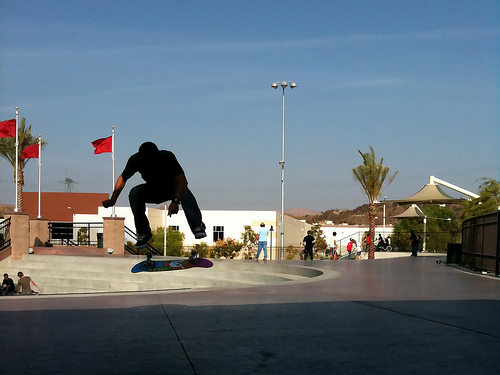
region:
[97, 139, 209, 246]
Guy in black skating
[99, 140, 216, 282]
Guy performing an ollie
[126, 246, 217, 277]
Blue and purple skateboard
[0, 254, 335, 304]
Oval set of concrete stairs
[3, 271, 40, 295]
Two people sitting on stairs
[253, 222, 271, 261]
Guy wearing a baby blue shirt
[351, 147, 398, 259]
Brown and green palm tree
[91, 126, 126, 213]
White flag pole with red flag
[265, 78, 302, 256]
Tall silver light pole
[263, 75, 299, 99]
Three lights at the top of light pole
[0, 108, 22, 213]
a nondescript red flag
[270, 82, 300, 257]
a very tall street lamp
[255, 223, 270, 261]
a man in blue walking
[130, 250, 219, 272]
a flipped skateboard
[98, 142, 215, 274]
a man doing a trick on his skateboard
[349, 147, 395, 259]
a warm weather tree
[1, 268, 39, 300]
two people sitting side by side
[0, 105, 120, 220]
three red flags waving side by side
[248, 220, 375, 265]
a group of distant people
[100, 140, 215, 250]
a man jumping in the air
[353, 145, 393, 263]
A palm tree.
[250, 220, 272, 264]
A man in jeans and a light blue shirt.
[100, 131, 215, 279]
A skateboarder doing tricks.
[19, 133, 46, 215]
A red flag.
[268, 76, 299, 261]
Outdoor lights.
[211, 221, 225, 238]
A window.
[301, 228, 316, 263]
A person dressed in black.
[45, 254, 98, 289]
The concrete stairs.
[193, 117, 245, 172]
The clear blue sky.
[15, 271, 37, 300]
A person sitting down with a brown shirt on.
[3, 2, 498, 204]
blue of daytime sky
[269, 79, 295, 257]
three lights on pole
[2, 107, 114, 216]
three red flags on pole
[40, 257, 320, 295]
circular steps under platform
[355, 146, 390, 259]
leaves on palm tree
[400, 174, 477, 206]
umbrella on white pole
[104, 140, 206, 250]
man jumping in the air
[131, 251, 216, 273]
bottom of airborne skateboard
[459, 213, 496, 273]
frame of brown fence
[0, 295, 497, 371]
shadow on cement surface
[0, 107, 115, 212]
three red flags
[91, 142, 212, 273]
a man jumping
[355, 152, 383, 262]
a plam tree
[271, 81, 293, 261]
a street high lamp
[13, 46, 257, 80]
a blue sky in the background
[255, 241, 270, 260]
this jean is blue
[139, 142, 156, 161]
the head of the skater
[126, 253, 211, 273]
a beautiful skateboard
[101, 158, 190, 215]
the arms of the skater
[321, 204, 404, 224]
mountains in the distance